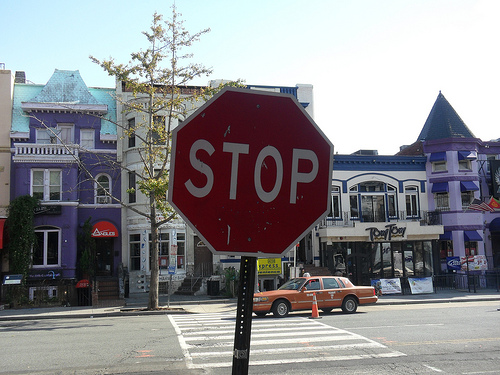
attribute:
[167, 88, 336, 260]
sign — red, white, stop, octagon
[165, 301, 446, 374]
lines — white, crosswalk, painted, cross walk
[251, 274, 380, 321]
taxi — orange, cab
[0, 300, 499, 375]
street — gray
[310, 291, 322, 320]
cone — orange, traffic, white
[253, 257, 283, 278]
sign — yellow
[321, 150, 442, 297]
building — white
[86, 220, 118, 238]
awning — red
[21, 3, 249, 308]
tree — large, tall, one, across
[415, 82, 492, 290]
building — purple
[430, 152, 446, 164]
awning — purple, blue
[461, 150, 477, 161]
awning — purple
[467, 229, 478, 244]
awning — purple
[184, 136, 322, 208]
stop — white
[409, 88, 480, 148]
roof — pyramid, blue, conical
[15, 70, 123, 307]
building — purple, white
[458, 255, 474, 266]
sign — red, business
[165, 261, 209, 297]
fence — metal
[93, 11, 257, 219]
leaves — few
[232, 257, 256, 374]
pole — metal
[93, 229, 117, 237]
designs — white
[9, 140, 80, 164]
balcony — white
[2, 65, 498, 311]
establishments — commercial